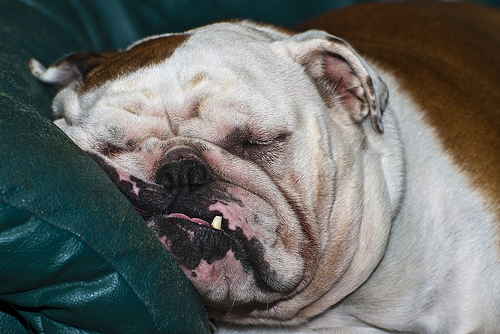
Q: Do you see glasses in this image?
A: No, there are no glasses.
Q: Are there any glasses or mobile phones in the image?
A: No, there are no glasses or mobile phones.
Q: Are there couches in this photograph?
A: Yes, there is a couch.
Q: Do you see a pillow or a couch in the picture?
A: Yes, there is a couch.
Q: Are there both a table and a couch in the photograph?
A: No, there is a couch but no tables.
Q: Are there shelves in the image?
A: No, there are no shelves.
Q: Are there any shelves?
A: No, there are no shelves.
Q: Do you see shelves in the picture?
A: No, there are no shelves.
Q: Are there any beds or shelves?
A: No, there are no shelves or beds.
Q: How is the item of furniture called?
A: The piece of furniture is a couch.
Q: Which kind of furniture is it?
A: The piece of furniture is a couch.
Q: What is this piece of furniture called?
A: This is a couch.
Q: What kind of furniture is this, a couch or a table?
A: This is a couch.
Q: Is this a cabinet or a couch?
A: This is a couch.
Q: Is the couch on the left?
A: Yes, the couch is on the left of the image.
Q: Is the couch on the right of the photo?
A: No, the couch is on the left of the image.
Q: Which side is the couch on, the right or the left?
A: The couch is on the left of the image.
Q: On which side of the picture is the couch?
A: The couch is on the left of the image.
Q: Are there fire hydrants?
A: No, there are no fire hydrants.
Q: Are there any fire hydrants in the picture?
A: No, there are no fire hydrants.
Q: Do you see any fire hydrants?
A: No, there are no fire hydrants.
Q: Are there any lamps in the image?
A: No, there are no lamps.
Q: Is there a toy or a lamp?
A: No, there are no lamps or toys.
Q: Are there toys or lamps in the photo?
A: No, there are no lamps or toys.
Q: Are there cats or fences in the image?
A: No, there are no cats or fences.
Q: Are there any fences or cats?
A: No, there are no cats or fences.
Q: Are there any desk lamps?
A: No, there are no desk lamps.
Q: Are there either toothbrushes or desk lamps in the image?
A: No, there are no desk lamps or toothbrushes.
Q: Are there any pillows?
A: Yes, there is a pillow.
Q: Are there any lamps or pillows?
A: Yes, there is a pillow.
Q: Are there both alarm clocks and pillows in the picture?
A: No, there is a pillow but no alarm clocks.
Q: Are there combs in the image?
A: No, there are no combs.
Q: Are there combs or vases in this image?
A: No, there are no combs or vases.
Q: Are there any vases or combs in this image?
A: No, there are no combs or vases.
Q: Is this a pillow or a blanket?
A: This is a pillow.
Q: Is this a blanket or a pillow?
A: This is a pillow.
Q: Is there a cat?
A: No, there are no cats.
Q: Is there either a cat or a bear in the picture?
A: No, there are no cats or bears.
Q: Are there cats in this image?
A: No, there are no cats.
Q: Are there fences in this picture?
A: No, there are no fences.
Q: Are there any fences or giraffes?
A: No, there are no fences or giraffes.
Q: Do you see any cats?
A: No, there are no cats.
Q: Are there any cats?
A: No, there are no cats.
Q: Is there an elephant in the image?
A: No, there are no elephants.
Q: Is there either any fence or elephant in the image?
A: No, there are no elephants or fences.